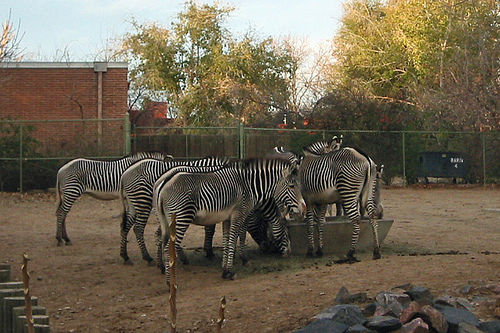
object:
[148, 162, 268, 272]
zebra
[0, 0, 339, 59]
clouds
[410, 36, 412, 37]
leaves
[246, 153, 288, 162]
mane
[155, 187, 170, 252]
tail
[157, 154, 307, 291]
zebra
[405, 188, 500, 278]
ground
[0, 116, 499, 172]
fence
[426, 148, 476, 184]
bin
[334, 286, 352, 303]
rocks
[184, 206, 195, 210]
stripes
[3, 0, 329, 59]
sky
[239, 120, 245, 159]
pole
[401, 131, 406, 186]
pole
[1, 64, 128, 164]
wall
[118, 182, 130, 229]
tail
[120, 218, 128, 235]
tip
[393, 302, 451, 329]
rock pile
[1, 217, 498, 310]
surface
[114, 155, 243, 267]
zebra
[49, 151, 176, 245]
zebra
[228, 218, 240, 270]
leg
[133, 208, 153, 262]
leg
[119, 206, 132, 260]
leg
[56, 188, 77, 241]
leg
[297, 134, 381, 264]
zebra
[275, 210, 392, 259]
metal bin